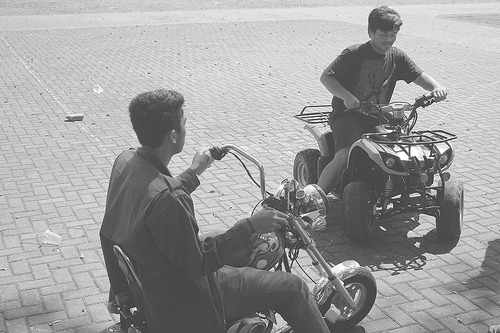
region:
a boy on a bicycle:
[80, 87, 386, 330]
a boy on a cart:
[285, 1, 470, 252]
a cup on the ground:
[39, 224, 66, 251]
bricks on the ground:
[2, 2, 499, 332]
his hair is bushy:
[362, 7, 407, 40]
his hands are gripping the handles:
[338, 82, 448, 129]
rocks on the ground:
[65, 112, 86, 126]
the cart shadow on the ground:
[282, 190, 436, 280]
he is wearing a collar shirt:
[86, 144, 258, 331]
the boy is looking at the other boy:
[80, 74, 375, 330]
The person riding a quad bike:
[294, 7, 471, 239]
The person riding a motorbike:
[99, 90, 378, 331]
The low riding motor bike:
[108, 143, 380, 330]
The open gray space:
[0, 0, 498, 332]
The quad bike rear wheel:
[294, 147, 324, 186]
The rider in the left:
[98, 88, 336, 329]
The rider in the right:
[313, 7, 448, 202]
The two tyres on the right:
[340, 178, 493, 238]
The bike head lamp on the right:
[285, 180, 330, 232]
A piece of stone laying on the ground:
[62, 113, 87, 123]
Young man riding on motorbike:
[92, 84, 332, 331]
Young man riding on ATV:
[284, 27, 470, 237]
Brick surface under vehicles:
[3, 23, 498, 331]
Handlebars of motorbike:
[209, 135, 320, 222]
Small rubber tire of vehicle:
[307, 246, 402, 331]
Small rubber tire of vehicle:
[281, 145, 326, 202]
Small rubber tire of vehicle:
[345, 178, 385, 248]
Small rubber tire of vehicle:
[428, 178, 473, 240]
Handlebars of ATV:
[356, 96, 449, 134]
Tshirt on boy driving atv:
[325, 27, 434, 132]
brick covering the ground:
[6, 26, 308, 107]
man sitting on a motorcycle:
[92, 92, 354, 330]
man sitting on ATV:
[302, 15, 459, 242]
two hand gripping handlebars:
[320, 80, 463, 119]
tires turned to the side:
[336, 173, 478, 253]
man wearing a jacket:
[103, 88, 270, 332]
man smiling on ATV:
[318, 6, 450, 134]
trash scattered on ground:
[31, 222, 66, 250]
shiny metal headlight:
[281, 175, 338, 229]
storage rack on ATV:
[364, 119, 458, 159]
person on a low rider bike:
[99, 89, 376, 328]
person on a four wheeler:
[293, 2, 463, 240]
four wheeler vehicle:
[286, 92, 463, 243]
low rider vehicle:
[101, 143, 376, 331]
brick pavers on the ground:
[1, 27, 492, 330]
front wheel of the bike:
[314, 259, 382, 331]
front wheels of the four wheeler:
[340, 176, 463, 237]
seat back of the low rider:
[111, 242, 148, 328]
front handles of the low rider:
[210, 146, 303, 230]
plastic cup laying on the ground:
[42, 229, 61, 244]